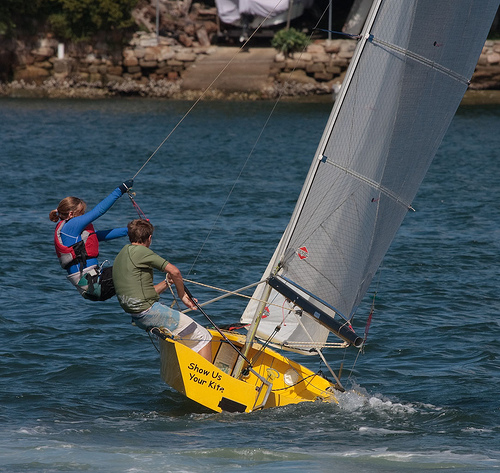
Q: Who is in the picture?
A: A man and a woman.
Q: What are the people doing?
A: Sailing.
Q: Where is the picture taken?
A: An ocean.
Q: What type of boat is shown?
A: Sailing boat.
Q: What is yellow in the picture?
A: Boat.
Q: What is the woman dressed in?
A: A wetsuit.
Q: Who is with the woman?
A: A man.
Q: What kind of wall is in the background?
A: A stone wall.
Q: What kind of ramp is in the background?
A: Boat.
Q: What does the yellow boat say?
A: Show Us Your Kite.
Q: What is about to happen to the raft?
A: Sink.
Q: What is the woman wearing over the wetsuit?
A: A life vest.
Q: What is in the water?
A: Waves.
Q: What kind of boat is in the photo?
A: Sailboat.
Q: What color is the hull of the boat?
A: Yellow.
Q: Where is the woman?
A: Far left of boat.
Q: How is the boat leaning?
A: To the right.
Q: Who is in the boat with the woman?
A: A man.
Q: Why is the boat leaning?
A: Wind.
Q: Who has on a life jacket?
A: Woman.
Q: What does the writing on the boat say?
A: Show us your kite.